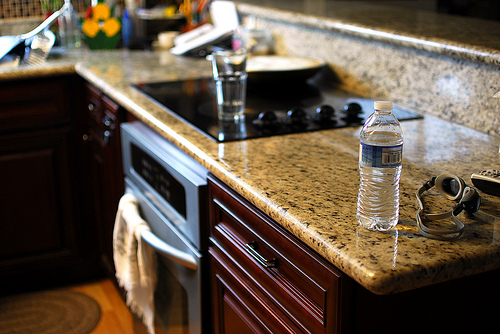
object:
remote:
[467, 169, 500, 199]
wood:
[93, 278, 136, 333]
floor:
[2, 279, 134, 330]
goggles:
[415, 171, 478, 241]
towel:
[108, 193, 159, 332]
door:
[106, 110, 211, 331]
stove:
[122, 62, 426, 144]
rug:
[0, 292, 99, 334]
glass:
[211, 53, 252, 123]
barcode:
[380, 149, 403, 165]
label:
[358, 142, 404, 168]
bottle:
[354, 101, 403, 231]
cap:
[373, 100, 394, 111]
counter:
[1, 36, 500, 334]